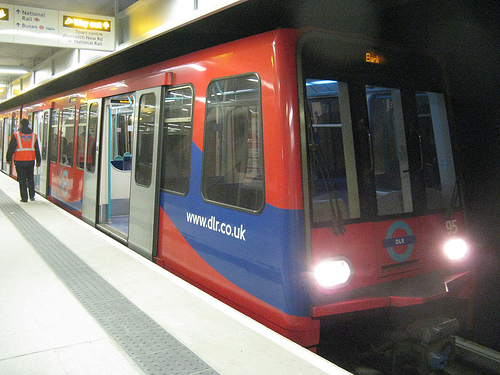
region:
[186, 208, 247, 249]
www.dlr.co.uk on the train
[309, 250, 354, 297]
bright front train light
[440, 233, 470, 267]
bright front train light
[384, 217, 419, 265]
light blue circle on the front of the train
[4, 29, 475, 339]
blue and red train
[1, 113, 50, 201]
man standing on train platform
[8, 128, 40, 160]
orange and silver vest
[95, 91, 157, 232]
opened door of the train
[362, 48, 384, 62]
"Bark" displayed in the led screen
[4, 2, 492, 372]
a train is at a station in the underground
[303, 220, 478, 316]
the headlights are on the train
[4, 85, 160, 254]
the doors are open at the station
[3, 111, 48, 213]
a worker is walking on the plaform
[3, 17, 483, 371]
the train is red and blue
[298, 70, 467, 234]
the front windows of the train have handles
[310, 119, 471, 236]
windshield wipers are on the train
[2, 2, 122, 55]
a directional sign is hanging from the ceiling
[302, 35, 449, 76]
a destination marquee is on the front of the train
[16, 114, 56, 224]
A man standing next to the train.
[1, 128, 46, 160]
the person is wearing an orange vest.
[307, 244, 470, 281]
Headlights of the train are on.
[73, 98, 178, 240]
The door of the train is open.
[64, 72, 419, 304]
The train is red and blue.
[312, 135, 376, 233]
Wipers on the front windshield of the train.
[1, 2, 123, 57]
A sign above the train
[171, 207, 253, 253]
White writing on the side of the train.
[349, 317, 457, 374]
The train is on the tracks.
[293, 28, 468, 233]
the windshield of a train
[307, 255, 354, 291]
the headlight of a train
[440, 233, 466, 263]
the headlight of a train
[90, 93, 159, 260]
the door of a subway train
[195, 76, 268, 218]
a window on a subway train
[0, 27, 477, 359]
a subway train car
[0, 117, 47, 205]
a safety officer on a train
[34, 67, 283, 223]
a group of windows on a subway train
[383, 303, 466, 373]
a coupler on a train car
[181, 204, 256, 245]
website for rail road line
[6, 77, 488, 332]
Red and blue train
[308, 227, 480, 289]
Head lights of the train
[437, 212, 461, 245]
Bus number ninety five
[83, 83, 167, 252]
Train's door is open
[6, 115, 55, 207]
Man wearing orange vest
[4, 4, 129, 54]
Signs giving directions to passengers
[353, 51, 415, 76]
Desination of the bus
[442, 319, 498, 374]
Train track in front of train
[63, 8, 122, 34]
Sign pointing the way out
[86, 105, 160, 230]
open door of the train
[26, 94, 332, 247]
red subway on rial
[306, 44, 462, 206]
frontal window of the train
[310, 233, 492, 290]
frontal light in the train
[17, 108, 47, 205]
man whit uniform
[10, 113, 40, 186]
man standin on the station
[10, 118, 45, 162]
man whit a black sweter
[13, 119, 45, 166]
man wearin a orange vest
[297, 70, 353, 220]
glass window on the red train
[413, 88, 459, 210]
glass window on the red train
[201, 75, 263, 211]
glass window on the red train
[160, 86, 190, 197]
glass window on the red train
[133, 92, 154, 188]
glass window on the red train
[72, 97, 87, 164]
glass window on the red train